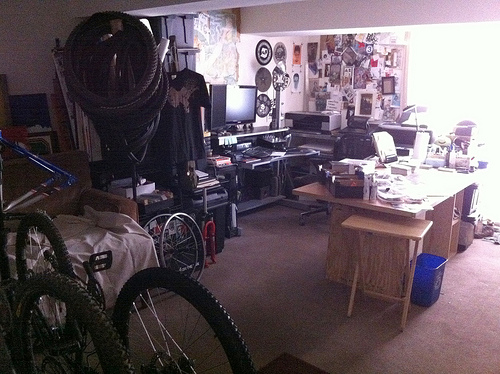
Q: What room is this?
A: Basement office.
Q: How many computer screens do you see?
A: 2.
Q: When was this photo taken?
A: During daylight.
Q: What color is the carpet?
A: Light red.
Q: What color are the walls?
A: White.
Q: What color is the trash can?
A: Blue.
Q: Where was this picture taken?
A: In a garage.